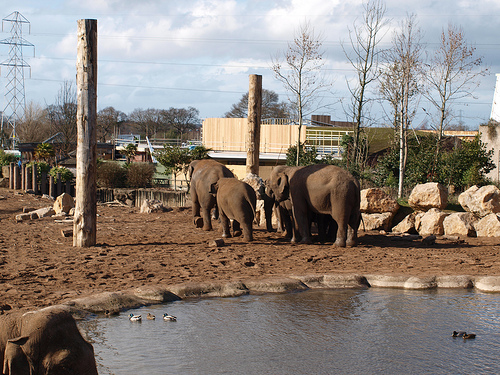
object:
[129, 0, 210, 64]
clouds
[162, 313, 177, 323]
duck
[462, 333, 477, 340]
duck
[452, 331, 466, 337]
duck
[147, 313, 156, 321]
duck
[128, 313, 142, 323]
duck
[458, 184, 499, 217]
rock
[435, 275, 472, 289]
rock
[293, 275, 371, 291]
rock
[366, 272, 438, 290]
rock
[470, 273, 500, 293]
rock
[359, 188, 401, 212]
rock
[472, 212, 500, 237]
rock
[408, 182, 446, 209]
rock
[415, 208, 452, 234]
rock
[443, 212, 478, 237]
rock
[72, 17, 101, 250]
stump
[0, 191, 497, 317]
dirt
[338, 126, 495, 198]
bushes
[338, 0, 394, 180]
trees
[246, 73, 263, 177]
pole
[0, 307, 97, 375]
head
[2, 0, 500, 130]
sky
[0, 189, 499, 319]
ground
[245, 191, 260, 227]
tail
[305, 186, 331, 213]
stomach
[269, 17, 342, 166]
trees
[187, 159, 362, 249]
elephant group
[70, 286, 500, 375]
pond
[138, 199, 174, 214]
stones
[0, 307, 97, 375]
elephant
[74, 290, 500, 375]
water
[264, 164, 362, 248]
elephant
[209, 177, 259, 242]
elephant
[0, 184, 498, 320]
sand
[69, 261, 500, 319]
barrier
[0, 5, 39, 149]
tower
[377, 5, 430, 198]
trees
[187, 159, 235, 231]
elephant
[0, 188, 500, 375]
area